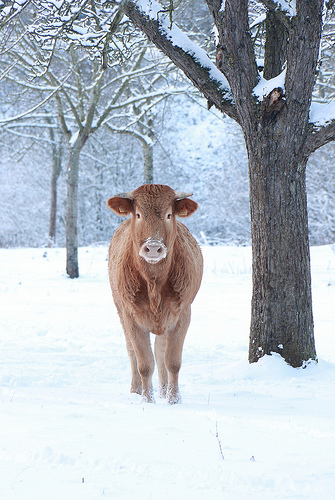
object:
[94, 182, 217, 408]
cow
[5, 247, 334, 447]
snow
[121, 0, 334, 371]
tree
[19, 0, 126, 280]
trees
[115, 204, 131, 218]
tag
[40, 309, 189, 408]
tracks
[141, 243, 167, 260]
nose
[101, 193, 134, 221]
ears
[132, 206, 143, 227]
eyes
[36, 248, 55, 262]
twig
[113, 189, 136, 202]
horns